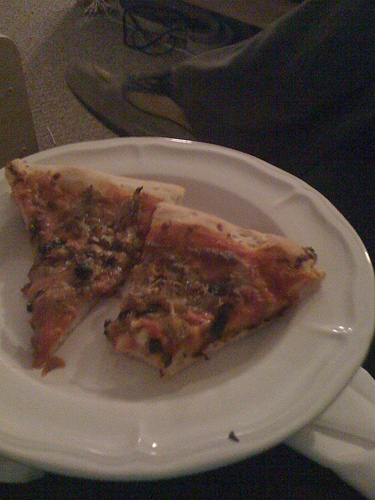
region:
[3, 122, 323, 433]
white plate with pizza on it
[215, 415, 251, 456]
small topping of pizza on plate side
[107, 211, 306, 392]
slice of pizza missing end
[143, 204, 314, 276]
brown crust of pizza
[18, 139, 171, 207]
brown crust of pizza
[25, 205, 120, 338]
different toppings on pizza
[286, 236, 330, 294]
chunk taken out of crust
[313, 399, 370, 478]
white folded napkin on table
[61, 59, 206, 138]
shoe of person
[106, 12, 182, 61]
cords on the floor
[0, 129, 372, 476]
a white plate with pizza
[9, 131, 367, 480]
a round white plate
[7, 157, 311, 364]
two slices of pizza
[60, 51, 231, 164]
a brown and black shoe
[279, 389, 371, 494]
a white napkin under plate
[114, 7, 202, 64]
a black cord on the ground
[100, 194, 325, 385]
a partially eaten pizza slice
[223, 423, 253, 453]
a small black spot on plate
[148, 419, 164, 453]
reflection of light on plate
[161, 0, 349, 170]
a brown pant leg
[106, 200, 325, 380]
A piece of pizza white a bite taken out of it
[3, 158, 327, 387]
Two pieces of pizza on a white plate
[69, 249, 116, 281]
Toppings on a piece of pizza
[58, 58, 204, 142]
Shoe being worn by a person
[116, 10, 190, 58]
Electrical wire on the carpeted floor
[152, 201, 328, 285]
Crust of a piece of pizza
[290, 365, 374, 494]
A white napkin resting under a white plate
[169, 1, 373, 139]
Pant leg of a person sitting at the table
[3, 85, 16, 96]
Metal bolt screwed into furniture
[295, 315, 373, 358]
The raised edge of a white plate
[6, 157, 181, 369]
a slice of pizza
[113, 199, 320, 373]
a slice of pizza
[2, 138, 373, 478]
pizza on a ceramic plate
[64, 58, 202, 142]
a person's shoe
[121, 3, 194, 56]
a metal leg for a table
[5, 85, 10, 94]
small metal screw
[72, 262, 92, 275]
olive on a pizza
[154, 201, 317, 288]
crust of a pizza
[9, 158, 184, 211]
crust of a slice of pizza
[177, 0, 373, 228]
a person's pant leg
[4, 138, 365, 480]
plate with two pieces of pizza on it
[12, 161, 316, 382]
pizza with red sauce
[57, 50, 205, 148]
a persons foot with a shoe on it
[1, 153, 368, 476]
thick white plate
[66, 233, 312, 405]
pizza with a bite taken from it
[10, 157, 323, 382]
pizza with toppings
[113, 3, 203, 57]
black cords on the floor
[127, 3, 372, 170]
long pants on a persons leg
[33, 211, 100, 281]
black toppings on a pizza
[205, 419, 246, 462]
a crumb from the pizza